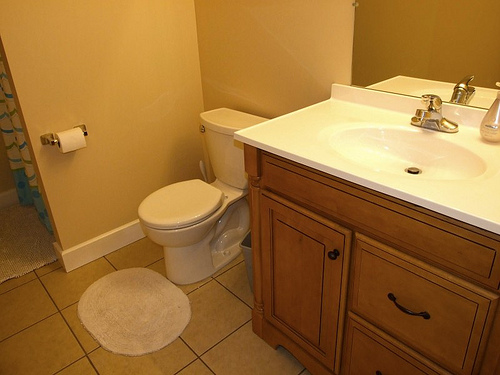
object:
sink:
[231, 94, 498, 231]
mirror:
[352, 0, 499, 117]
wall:
[2, 0, 353, 256]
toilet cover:
[138, 179, 224, 229]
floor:
[1, 211, 282, 375]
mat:
[72, 263, 192, 354]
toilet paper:
[52, 128, 88, 153]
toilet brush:
[199, 161, 208, 181]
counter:
[234, 74, 498, 375]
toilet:
[136, 108, 267, 289]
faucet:
[411, 94, 458, 133]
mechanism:
[198, 124, 206, 135]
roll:
[60, 128, 83, 150]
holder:
[41, 126, 89, 147]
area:
[0, 2, 498, 366]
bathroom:
[0, 2, 496, 372]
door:
[258, 192, 355, 366]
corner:
[178, 0, 221, 196]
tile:
[6, 249, 302, 371]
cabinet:
[240, 151, 500, 375]